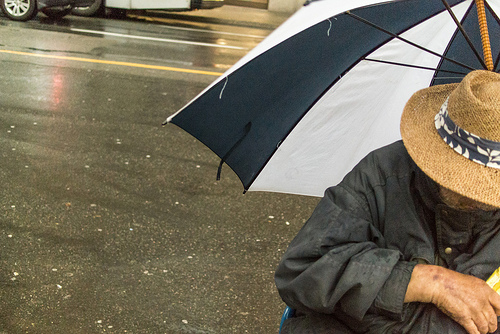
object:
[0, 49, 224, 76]
line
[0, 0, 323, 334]
road